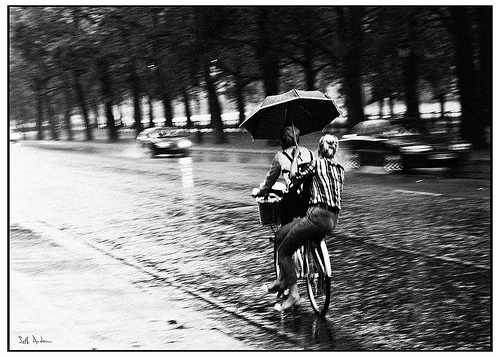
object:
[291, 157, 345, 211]
shirt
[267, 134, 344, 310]
woman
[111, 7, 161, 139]
tree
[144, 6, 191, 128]
tree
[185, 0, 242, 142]
tree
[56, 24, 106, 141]
tree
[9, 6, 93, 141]
tree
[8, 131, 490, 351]
road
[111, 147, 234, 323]
street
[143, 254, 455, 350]
rain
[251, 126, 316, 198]
woman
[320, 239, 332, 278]
fender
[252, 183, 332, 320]
bike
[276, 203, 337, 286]
pants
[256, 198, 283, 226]
basket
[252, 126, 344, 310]
people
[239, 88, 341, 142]
umbrella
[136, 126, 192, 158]
car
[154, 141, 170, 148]
headlight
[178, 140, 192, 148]
headlight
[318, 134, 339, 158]
hair